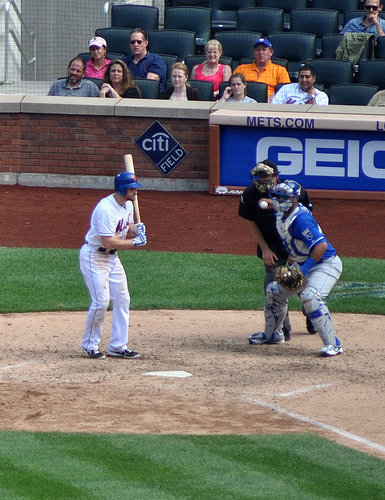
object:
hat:
[254, 37, 271, 47]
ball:
[259, 199, 268, 211]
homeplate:
[142, 368, 192, 383]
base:
[140, 367, 194, 381]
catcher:
[247, 178, 343, 356]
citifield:
[140, 132, 184, 177]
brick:
[2, 114, 209, 179]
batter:
[77, 170, 147, 360]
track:
[1, 309, 383, 465]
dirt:
[0, 305, 382, 460]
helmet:
[269, 178, 300, 212]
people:
[48, 2, 381, 111]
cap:
[252, 38, 275, 48]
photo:
[3, 2, 383, 498]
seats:
[68, 2, 382, 106]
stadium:
[2, 4, 381, 106]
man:
[75, 172, 147, 361]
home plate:
[140, 370, 196, 379]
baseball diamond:
[3, 339, 356, 404]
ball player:
[78, 169, 149, 365]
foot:
[79, 343, 106, 358]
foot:
[105, 342, 138, 361]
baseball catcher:
[246, 179, 346, 360]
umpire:
[237, 161, 316, 338]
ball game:
[3, 107, 382, 499]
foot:
[318, 341, 346, 359]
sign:
[215, 123, 383, 198]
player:
[75, 171, 147, 364]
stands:
[40, 3, 383, 115]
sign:
[134, 118, 188, 174]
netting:
[1, 2, 383, 117]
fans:
[275, 64, 329, 109]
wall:
[5, 91, 383, 200]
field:
[3, 186, 379, 499]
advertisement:
[215, 119, 383, 194]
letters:
[253, 130, 302, 181]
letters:
[301, 134, 345, 178]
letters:
[345, 136, 360, 179]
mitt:
[274, 261, 307, 291]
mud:
[3, 377, 311, 436]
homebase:
[140, 364, 194, 385]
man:
[233, 36, 289, 101]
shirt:
[234, 63, 288, 102]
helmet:
[115, 171, 138, 195]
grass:
[36, 436, 304, 486]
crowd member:
[191, 38, 232, 93]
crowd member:
[98, 58, 140, 100]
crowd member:
[81, 37, 113, 79]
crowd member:
[340, 1, 384, 36]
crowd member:
[217, 72, 256, 104]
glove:
[132, 234, 146, 244]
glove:
[133, 222, 145, 233]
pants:
[79, 244, 129, 349]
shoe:
[82, 346, 107, 359]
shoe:
[106, 340, 146, 368]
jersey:
[287, 214, 337, 260]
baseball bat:
[122, 152, 147, 245]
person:
[70, 168, 152, 362]